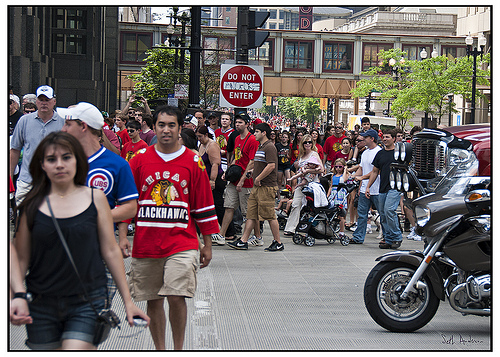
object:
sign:
[219, 63, 264, 109]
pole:
[233, 5, 251, 116]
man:
[116, 105, 220, 351]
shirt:
[114, 142, 221, 259]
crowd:
[0, 82, 423, 252]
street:
[213, 218, 493, 349]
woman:
[7, 130, 153, 351]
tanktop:
[24, 186, 110, 298]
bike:
[362, 157, 492, 334]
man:
[343, 129, 387, 245]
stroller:
[292, 177, 361, 247]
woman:
[282, 133, 326, 235]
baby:
[287, 158, 322, 189]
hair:
[13, 130, 90, 236]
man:
[208, 113, 265, 247]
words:
[229, 92, 254, 100]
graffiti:
[225, 81, 261, 91]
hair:
[152, 104, 184, 132]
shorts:
[126, 248, 202, 303]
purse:
[44, 195, 122, 346]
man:
[59, 101, 139, 310]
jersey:
[85, 143, 141, 231]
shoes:
[264, 239, 285, 252]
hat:
[56, 101, 106, 131]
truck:
[409, 122, 492, 194]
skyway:
[116, 20, 477, 98]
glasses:
[303, 140, 313, 144]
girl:
[327, 158, 350, 239]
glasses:
[334, 165, 344, 168]